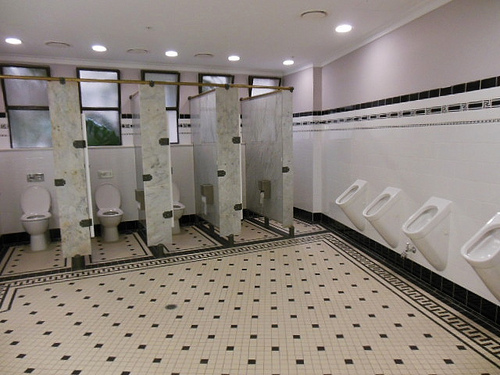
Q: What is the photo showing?
A: It is showing a bathroom.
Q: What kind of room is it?
A: It is a bathroom.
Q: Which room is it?
A: It is a bathroom.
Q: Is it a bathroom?
A: Yes, it is a bathroom.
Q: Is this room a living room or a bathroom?
A: It is a bathroom.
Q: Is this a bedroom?
A: No, it is a bathroom.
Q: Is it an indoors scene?
A: Yes, it is indoors.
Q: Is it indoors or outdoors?
A: It is indoors.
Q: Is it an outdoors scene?
A: No, it is indoors.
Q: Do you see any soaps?
A: No, there are no soaps.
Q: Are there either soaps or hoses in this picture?
A: No, there are no soaps or hoses.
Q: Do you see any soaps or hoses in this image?
A: No, there are no soaps or hoses.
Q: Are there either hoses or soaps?
A: No, there are no soaps or hoses.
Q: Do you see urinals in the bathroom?
A: Yes, there is a urinal in the bathroom.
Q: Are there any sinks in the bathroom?
A: No, there is a urinal in the bathroom.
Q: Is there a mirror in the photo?
A: No, there are no mirrors.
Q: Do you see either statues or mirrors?
A: No, there are no mirrors or statues.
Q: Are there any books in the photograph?
A: No, there are no books.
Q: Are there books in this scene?
A: No, there are no books.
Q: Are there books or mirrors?
A: No, there are no books or mirrors.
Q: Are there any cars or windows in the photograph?
A: Yes, there is a window.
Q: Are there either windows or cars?
A: Yes, there is a window.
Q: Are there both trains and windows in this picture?
A: No, there is a window but no trains.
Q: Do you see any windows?
A: Yes, there is a window.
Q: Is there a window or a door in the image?
A: Yes, there is a window.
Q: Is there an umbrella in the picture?
A: No, there are no umbrellas.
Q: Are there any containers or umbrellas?
A: No, there are no umbrellas or containers.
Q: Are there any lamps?
A: No, there are no lamps.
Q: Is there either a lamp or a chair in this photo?
A: No, there are no lamps or chairs.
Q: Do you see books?
A: No, there are no books.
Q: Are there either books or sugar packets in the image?
A: No, there are no books or sugar packets.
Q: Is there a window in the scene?
A: Yes, there is a window.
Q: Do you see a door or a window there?
A: Yes, there is a window.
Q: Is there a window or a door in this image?
A: Yes, there is a window.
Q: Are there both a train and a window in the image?
A: No, there is a window but no trains.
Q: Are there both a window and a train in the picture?
A: No, there is a window but no trains.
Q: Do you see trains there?
A: No, there are no trains.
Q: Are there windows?
A: Yes, there is a window.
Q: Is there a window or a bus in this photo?
A: Yes, there is a window.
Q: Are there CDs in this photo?
A: No, there are no cds.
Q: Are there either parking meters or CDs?
A: No, there are no CDs or parking meters.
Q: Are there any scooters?
A: No, there are no scooters.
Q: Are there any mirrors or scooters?
A: No, there are no scooters or mirrors.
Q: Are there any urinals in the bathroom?
A: Yes, there is a urinal in the bathroom.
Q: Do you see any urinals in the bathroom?
A: Yes, there is a urinal in the bathroom.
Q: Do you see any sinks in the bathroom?
A: No, there is a urinal in the bathroom.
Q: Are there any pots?
A: No, there are no pots.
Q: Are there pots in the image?
A: No, there are no pots.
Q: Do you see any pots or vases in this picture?
A: No, there are no pots or vases.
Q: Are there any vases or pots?
A: No, there are no pots or vases.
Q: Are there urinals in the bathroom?
A: Yes, there is a urinal in the bathroom.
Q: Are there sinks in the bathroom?
A: No, there is a urinal in the bathroom.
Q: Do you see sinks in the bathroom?
A: No, there is a urinal in the bathroom.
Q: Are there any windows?
A: Yes, there is a window.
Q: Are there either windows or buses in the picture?
A: Yes, there is a window.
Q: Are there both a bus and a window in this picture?
A: No, there is a window but no buses.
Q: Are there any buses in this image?
A: No, there are no buses.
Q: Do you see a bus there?
A: No, there are no buses.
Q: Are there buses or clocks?
A: No, there are no buses or clocks.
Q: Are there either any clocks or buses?
A: No, there are no buses or clocks.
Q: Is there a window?
A: Yes, there is a window.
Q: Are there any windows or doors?
A: Yes, there is a window.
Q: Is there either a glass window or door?
A: Yes, there is a glass window.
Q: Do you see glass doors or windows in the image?
A: Yes, there is a glass window.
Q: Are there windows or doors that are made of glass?
A: Yes, the window is made of glass.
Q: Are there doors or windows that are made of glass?
A: Yes, the window is made of glass.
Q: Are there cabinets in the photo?
A: No, there are no cabinets.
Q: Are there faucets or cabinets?
A: No, there are no cabinets or faucets.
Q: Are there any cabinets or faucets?
A: No, there are no cabinets or faucets.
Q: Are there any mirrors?
A: No, there are no mirrors.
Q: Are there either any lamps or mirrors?
A: No, there are no mirrors or lamps.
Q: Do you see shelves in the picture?
A: No, there are no shelves.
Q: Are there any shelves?
A: No, there are no shelves.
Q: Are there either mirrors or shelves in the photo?
A: No, there are no shelves or mirrors.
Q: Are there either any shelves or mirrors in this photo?
A: No, there are no shelves or mirrors.